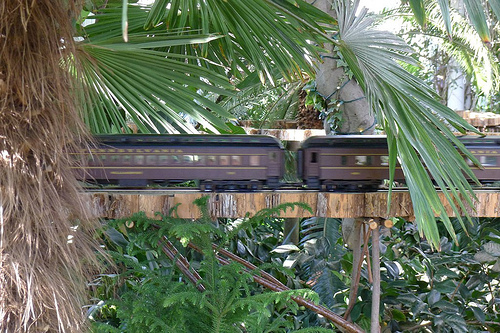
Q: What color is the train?
A: Brown.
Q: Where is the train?
A: On a bridge.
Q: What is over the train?
A: Leaves.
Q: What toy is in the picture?
A: Train.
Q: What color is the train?
A: Brown.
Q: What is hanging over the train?
A: Leaves.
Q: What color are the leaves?
A: Green.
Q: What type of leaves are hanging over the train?
A: Palm leaves.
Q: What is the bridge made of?
A: Wood.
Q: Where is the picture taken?
A: In a forest.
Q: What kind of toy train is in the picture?
A: Passenger train.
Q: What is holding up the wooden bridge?
A: Sticks.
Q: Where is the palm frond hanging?
A: In front of the train.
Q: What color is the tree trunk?
A: Brown.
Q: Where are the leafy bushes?
A: Below the train.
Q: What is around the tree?
A: A string of lights.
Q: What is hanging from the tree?
A: Palm fronds.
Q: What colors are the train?
A: Brown and black.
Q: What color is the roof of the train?
A: Black.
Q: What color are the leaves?
A: Green.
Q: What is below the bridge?
A: Leaves.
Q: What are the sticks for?
A: Holding the bridge.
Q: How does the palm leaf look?
A: Extended.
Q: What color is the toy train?
A: Brown.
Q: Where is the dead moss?
A: On a tree.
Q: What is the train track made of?
A: Bamboo.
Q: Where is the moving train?
A: On the tracks.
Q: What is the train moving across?
A: A bridge.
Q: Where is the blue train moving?
A: On bridge railroad tracks.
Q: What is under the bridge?
A: Trees with green leaves.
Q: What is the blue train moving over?
A: Bridge rail tracks.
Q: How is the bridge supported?
A: Wood crossbeams.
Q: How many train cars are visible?
A: Two.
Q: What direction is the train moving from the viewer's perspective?
A: To the right.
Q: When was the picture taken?
A: Daytime.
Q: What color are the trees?
A: Green.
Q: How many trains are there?
A: One.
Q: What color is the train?
A: Brown.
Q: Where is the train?
A: Under the trees.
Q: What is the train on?
A: Train tracks.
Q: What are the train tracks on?
A: Wood.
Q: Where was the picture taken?
A: Near trees.